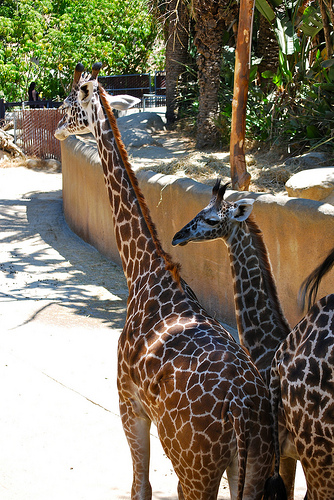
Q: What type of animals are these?
A: Giraffes.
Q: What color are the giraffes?
A: Brown and white.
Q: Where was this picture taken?
A: At the zoo.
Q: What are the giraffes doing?
A: Trying to find some shade.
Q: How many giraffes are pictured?
A: Three.